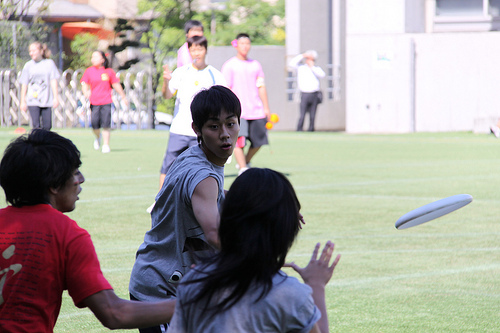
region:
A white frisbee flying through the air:
[390, 183, 481, 251]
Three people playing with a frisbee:
[7, 85, 346, 330]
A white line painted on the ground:
[345, 260, 490, 310]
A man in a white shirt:
[160, 34, 259, 159]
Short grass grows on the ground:
[310, 143, 380, 211]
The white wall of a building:
[371, 43, 492, 126]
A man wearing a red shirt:
[2, 145, 87, 331]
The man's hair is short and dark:
[7, 130, 84, 208]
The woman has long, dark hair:
[227, 178, 307, 282]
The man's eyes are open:
[201, 119, 251, 139]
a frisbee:
[384, 191, 484, 238]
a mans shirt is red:
[6, 208, 53, 323]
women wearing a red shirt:
[88, 67, 118, 110]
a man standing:
[288, 57, 331, 134]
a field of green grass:
[302, 138, 409, 196]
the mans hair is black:
[10, 148, 58, 181]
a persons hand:
[288, 241, 355, 298]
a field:
[314, 140, 392, 198]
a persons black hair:
[235, 187, 292, 275]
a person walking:
[22, 45, 71, 125]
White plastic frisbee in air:
[387, 189, 478, 235]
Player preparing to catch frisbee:
[164, 168, 345, 330]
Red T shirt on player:
[2, 203, 116, 332]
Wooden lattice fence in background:
[0, 63, 159, 132]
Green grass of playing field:
[1, 123, 496, 330]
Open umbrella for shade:
[50, 16, 121, 46]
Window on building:
[395, 2, 495, 37]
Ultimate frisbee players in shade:
[5, 87, 344, 327]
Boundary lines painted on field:
[333, 233, 495, 294]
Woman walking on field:
[76, 48, 129, 159]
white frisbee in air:
[381, 189, 488, 251]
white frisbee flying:
[387, 188, 479, 231]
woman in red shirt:
[79, 47, 131, 160]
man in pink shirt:
[227, 24, 280, 171]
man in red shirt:
[2, 124, 181, 331]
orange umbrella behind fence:
[59, 10, 119, 42]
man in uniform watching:
[282, 42, 325, 132]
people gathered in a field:
[0, 31, 467, 331]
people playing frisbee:
[2, 74, 340, 329]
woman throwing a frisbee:
[126, 70, 255, 328]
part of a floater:
[447, 208, 465, 219]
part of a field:
[389, 140, 391, 142]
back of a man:
[279, 289, 288, 302]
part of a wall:
[369, 64, 373, 72]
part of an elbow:
[108, 308, 112, 318]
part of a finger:
[322, 257, 330, 258]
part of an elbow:
[285, 293, 302, 314]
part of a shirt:
[241, 288, 248, 305]